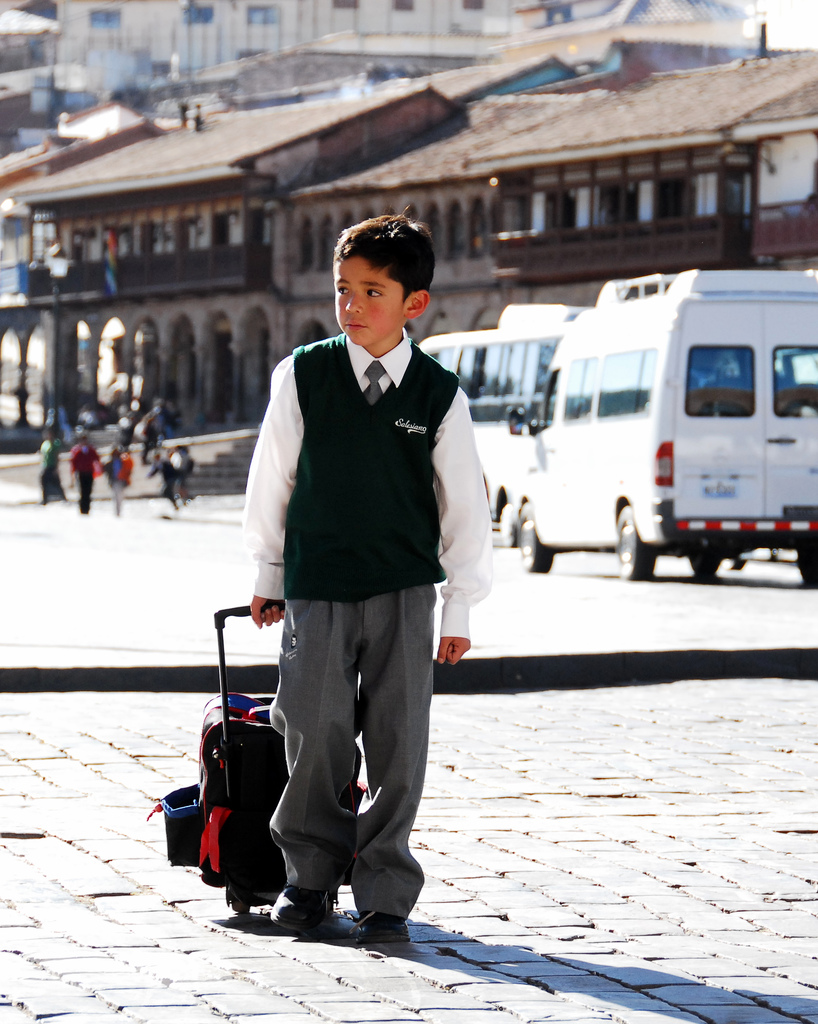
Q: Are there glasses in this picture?
A: No, there are no glasses.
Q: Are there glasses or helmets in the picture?
A: No, there are no glasses or helmets.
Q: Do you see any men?
A: No, there are no men.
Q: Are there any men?
A: No, there are no men.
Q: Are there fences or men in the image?
A: No, there are no men or fences.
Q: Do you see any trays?
A: No, there are no trays.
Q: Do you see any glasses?
A: No, there are no glasses.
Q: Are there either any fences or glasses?
A: No, there are no glasses or fences.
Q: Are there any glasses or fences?
A: No, there are no glasses or fences.